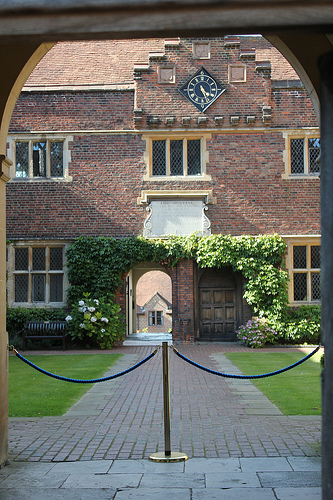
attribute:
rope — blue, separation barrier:
[171, 343, 325, 380]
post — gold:
[147, 340, 188, 462]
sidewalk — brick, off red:
[7, 345, 323, 461]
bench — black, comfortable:
[17, 319, 69, 347]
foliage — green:
[65, 233, 290, 343]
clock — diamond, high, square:
[178, 65, 228, 115]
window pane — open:
[30, 139, 49, 179]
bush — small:
[234, 315, 277, 347]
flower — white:
[86, 306, 95, 314]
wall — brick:
[8, 36, 322, 346]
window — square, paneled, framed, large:
[149, 138, 204, 178]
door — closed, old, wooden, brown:
[197, 264, 239, 342]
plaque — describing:
[148, 199, 206, 238]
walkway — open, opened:
[123, 262, 174, 344]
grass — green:
[223, 351, 324, 415]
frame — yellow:
[141, 130, 214, 182]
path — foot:
[134, 319, 170, 341]